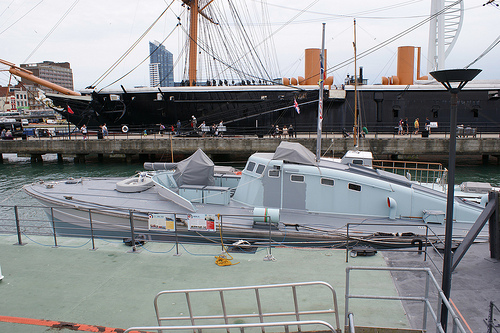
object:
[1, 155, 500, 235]
water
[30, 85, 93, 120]
bow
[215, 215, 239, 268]
rope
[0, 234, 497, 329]
ground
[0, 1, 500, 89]
sky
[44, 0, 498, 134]
ship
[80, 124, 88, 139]
person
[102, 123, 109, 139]
person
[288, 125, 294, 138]
person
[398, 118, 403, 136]
person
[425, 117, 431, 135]
person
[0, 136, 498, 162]
dock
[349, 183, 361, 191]
windows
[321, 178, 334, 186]
windows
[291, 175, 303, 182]
windows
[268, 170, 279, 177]
windows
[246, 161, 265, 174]
windows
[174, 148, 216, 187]
gray covers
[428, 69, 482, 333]
light post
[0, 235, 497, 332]
dock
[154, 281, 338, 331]
railings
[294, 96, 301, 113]
flag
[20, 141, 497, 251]
boat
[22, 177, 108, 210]
bow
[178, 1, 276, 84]
mast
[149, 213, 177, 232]
sign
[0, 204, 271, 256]
fence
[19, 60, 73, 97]
building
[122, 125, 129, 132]
hanging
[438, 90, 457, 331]
post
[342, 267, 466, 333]
rail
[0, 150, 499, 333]
docked